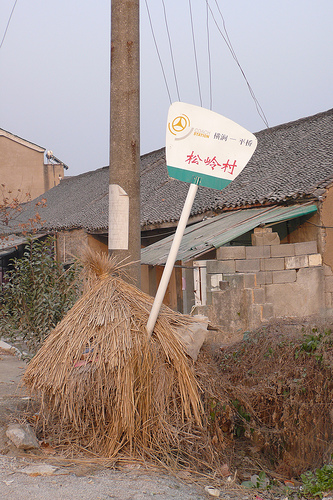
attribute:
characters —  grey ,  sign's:
[210, 126, 253, 146]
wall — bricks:
[198, 227, 331, 343]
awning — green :
[138, 203, 322, 262]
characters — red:
[186, 152, 238, 178]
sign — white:
[168, 87, 258, 199]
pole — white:
[150, 176, 200, 345]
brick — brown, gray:
[228, 239, 278, 263]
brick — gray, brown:
[270, 240, 298, 260]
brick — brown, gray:
[293, 243, 313, 260]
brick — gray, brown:
[233, 242, 266, 268]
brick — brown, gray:
[262, 254, 294, 275]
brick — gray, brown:
[283, 254, 312, 278]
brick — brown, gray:
[303, 244, 322, 276]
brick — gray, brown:
[265, 267, 325, 297]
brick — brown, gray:
[248, 266, 278, 289]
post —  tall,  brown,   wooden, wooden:
[109, 0, 140, 289]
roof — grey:
[0, 111, 322, 236]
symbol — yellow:
[166, 111, 191, 136]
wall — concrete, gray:
[193, 238, 331, 347]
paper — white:
[107, 184, 129, 249]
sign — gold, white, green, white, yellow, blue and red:
[163, 99, 258, 192]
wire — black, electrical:
[142, 0, 172, 107]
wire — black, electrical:
[160, 1, 183, 103]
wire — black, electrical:
[181, 3, 204, 106]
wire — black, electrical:
[201, 1, 214, 111]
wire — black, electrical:
[202, 3, 269, 127]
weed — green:
[301, 461, 332, 497]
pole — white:
[141, 181, 199, 335]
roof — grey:
[3, 108, 331, 230]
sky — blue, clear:
[1, 2, 329, 176]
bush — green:
[1, 236, 84, 364]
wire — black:
[144, 2, 174, 106]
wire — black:
[156, 1, 180, 101]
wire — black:
[185, 1, 202, 106]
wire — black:
[202, 2, 212, 112]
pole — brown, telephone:
[106, 0, 142, 285]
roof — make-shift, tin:
[134, 204, 312, 263]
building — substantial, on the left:
[0, 125, 70, 198]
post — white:
[148, 185, 198, 334]